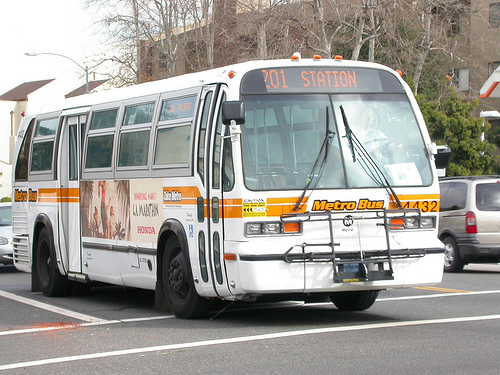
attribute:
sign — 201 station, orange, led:
[256, 65, 365, 93]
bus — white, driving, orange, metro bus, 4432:
[12, 58, 447, 318]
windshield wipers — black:
[296, 103, 402, 211]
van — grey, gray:
[436, 177, 497, 274]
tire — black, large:
[162, 236, 206, 318]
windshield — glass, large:
[239, 92, 434, 188]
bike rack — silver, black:
[280, 205, 426, 284]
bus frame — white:
[16, 106, 439, 286]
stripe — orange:
[15, 187, 445, 222]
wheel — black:
[31, 227, 63, 292]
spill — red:
[29, 319, 84, 337]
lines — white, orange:
[223, 192, 434, 217]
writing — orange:
[259, 68, 355, 90]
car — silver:
[1, 200, 14, 269]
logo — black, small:
[310, 198, 384, 210]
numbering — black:
[403, 201, 437, 213]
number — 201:
[261, 70, 288, 90]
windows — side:
[37, 103, 191, 174]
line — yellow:
[414, 284, 467, 297]